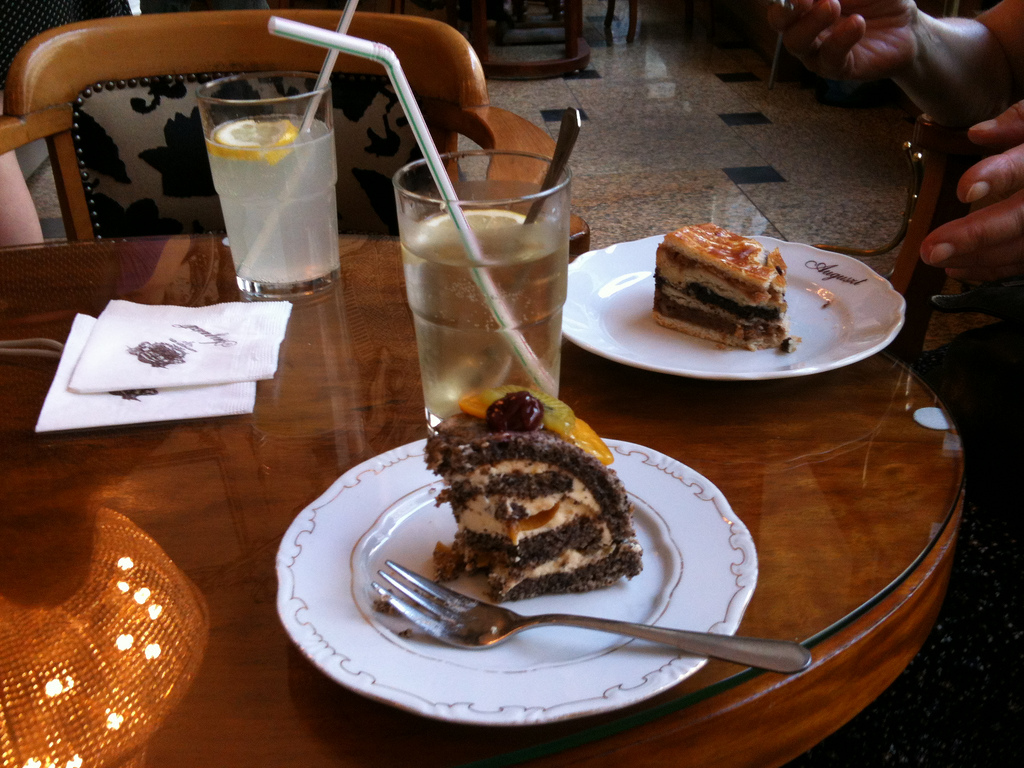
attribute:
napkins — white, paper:
[32, 293, 285, 433]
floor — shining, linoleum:
[528, 32, 893, 266]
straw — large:
[261, 13, 557, 407]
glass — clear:
[408, 195, 582, 453]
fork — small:
[364, 533, 807, 689]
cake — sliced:
[409, 371, 637, 618]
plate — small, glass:
[263, 408, 767, 734]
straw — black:
[513, 56, 578, 213]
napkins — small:
[19, 285, 298, 442]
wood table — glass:
[4, 232, 976, 763]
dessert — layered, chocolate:
[409, 384, 638, 588]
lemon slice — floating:
[209, 107, 296, 166]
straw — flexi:
[256, 1, 580, 426]